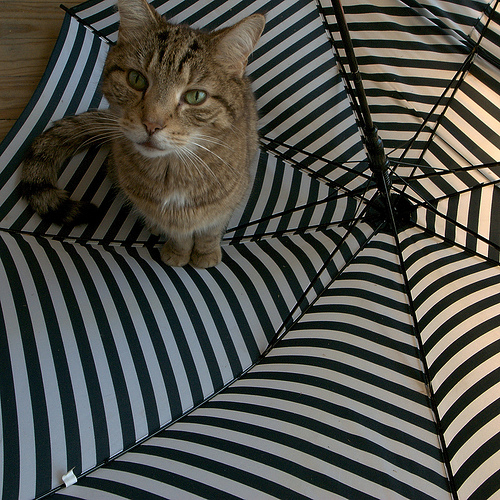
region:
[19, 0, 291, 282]
beautiful brown tabby cat looking up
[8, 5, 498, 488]
black and white striped umbrella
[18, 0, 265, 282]
cat sitting on open umbrella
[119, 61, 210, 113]
green eyes on brown cat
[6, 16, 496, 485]
umbrella is black and white and upside down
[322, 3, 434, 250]
black metal handle inside umbrella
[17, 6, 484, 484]
cat sitting inside open umbrella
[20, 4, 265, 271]
tan cat with black stripes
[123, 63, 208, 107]
green eyes with black slits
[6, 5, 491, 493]
black and white stripes across umbrella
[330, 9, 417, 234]
black pole reaching center of umbrella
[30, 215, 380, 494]
black wire separating two umbrella panels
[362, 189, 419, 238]
solid black center of umbrella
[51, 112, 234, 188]
white whiskers pointing out to side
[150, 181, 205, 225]
patch of white fur surrounded by tan fur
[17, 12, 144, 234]
curled tail to side of cat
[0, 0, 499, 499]
Cat is on the umbrella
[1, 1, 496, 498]
Umbrella is upside down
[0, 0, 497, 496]
Umbrella is black and white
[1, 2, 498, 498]
Black and white stripe umbrella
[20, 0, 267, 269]
Cat is looking up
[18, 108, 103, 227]
Black and brown tail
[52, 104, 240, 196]
Long white whiskers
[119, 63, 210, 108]
Two green eyes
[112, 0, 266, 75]
Two pointy ears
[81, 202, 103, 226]
Black tip tail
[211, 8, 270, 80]
left ear of the cat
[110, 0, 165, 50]
right ear of the cat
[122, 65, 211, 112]
eyeballs of the cat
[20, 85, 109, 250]
tail of the cat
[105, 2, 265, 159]
head of the cat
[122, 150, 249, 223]
torso of the cat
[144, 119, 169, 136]
nose of the cat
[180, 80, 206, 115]
one of the cats eyes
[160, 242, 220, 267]
front paws of the cat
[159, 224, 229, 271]
rear legs of the cat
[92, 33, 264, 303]
The cat is sitting on top of the umbrella.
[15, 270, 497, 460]
The umbrella is black and white.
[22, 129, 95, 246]
The cat tail is curved.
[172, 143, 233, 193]
The whiskers on the cat is long.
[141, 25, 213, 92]
The cat has long black stripes on top of head.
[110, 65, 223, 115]
The cay eyes are green.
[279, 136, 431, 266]
The wires of the umbrella.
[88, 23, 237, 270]
The cat is brown and black.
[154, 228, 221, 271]
The paws of the cat.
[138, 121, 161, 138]
The cat has a small nose.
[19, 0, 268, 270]
A cat sitting on an umbrella.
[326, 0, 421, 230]
A black metal pole.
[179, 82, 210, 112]
A left cat eye.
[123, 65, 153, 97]
A right cat eye.